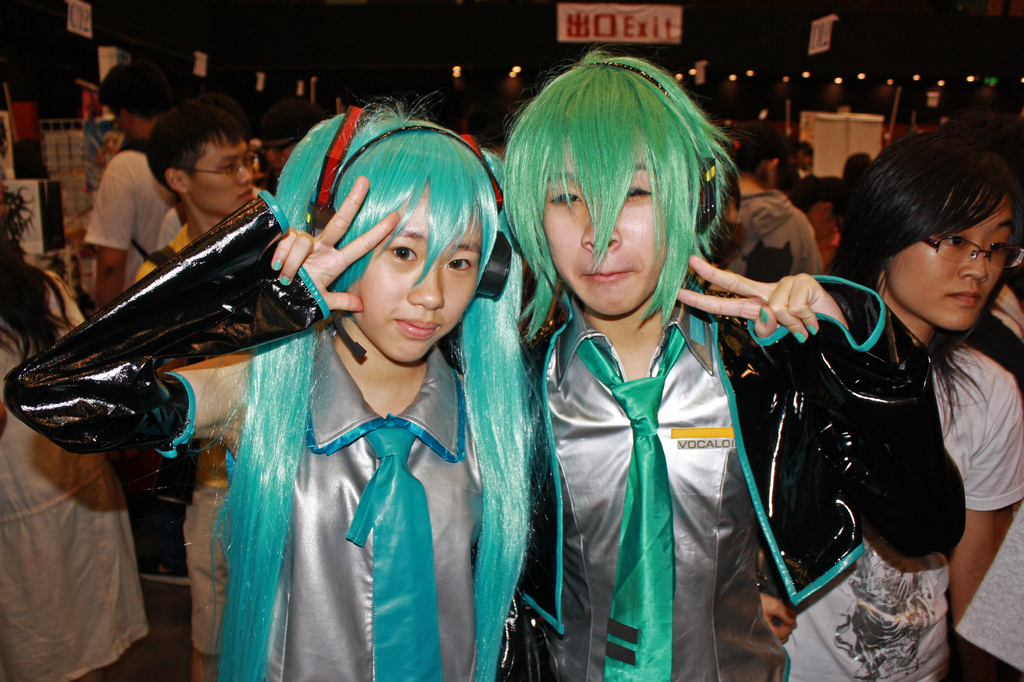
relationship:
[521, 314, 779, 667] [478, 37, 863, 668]
shirt on guy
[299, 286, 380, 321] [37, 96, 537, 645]
thumb on person